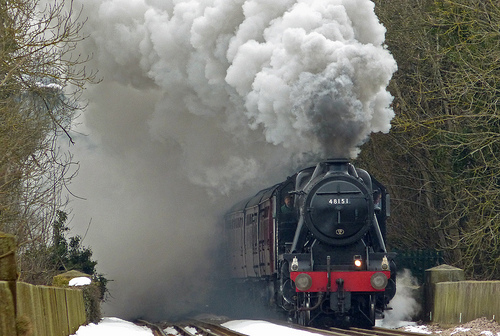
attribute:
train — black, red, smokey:
[200, 145, 391, 335]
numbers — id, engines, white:
[324, 194, 353, 208]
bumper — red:
[298, 269, 395, 296]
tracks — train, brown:
[144, 298, 423, 334]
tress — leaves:
[384, 10, 496, 269]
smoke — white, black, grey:
[62, 10, 389, 315]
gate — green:
[426, 267, 499, 325]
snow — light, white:
[88, 311, 268, 336]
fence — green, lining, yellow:
[6, 276, 86, 334]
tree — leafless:
[3, 1, 73, 271]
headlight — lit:
[293, 269, 390, 296]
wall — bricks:
[85, 279, 109, 331]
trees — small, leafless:
[390, 11, 500, 174]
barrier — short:
[35, 265, 111, 328]